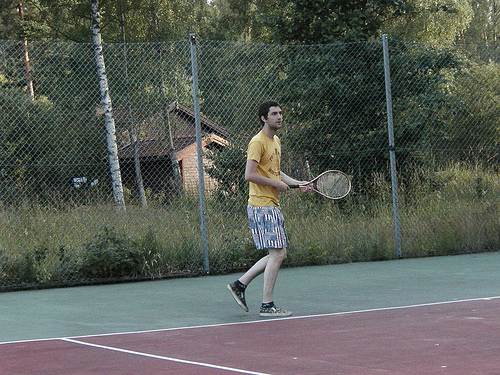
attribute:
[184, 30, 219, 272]
metal pole — thin, tall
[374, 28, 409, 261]
metal pole — tall, thin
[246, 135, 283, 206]
t-shirt — yellow, short-sleeved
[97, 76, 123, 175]
trunk — tall, white, black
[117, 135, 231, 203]
building — small, brown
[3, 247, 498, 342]
pavement — green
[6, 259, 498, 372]
tennis court — red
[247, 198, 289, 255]
shorts — patterned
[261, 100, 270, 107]
hair — short, black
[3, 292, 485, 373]
portion — red